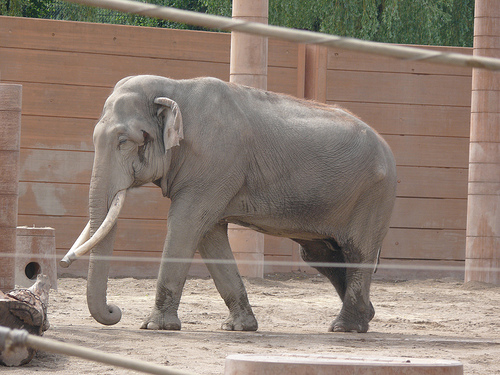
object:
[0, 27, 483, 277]
wall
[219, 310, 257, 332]
foot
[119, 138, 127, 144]
eye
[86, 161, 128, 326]
trunk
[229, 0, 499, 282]
structure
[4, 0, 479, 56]
trees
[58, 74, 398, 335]
elephant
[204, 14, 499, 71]
metal objects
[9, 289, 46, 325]
chain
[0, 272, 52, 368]
log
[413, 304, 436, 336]
ground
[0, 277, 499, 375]
dirt cage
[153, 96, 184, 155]
ear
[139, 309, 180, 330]
foot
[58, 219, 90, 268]
tusk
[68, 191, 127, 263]
tusk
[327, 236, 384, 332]
back leg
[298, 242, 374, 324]
back leg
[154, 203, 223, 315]
legs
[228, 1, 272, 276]
support beam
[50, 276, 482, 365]
dirt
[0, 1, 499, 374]
cage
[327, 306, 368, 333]
back foot